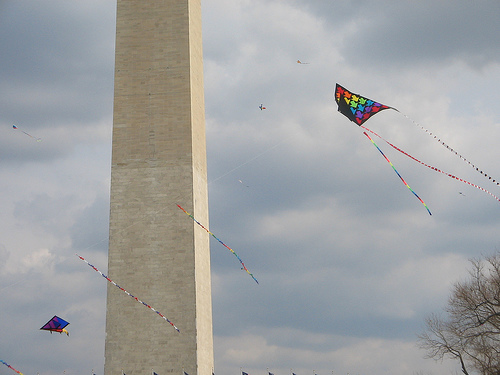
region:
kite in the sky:
[323, 84, 424, 161]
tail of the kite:
[158, 201, 260, 308]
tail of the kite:
[78, 255, 178, 328]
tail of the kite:
[353, 149, 424, 228]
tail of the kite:
[403, 160, 480, 202]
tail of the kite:
[421, 125, 491, 180]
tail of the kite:
[21, 130, 58, 144]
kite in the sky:
[33, 305, 83, 339]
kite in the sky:
[3, 118, 21, 141]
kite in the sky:
[307, 78, 389, 133]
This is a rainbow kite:
[317, 60, 497, 222]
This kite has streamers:
[353, 100, 494, 221]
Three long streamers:
[350, 87, 497, 229]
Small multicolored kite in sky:
[30, 309, 77, 342]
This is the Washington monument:
[102, 0, 229, 374]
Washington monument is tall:
[107, 0, 234, 374]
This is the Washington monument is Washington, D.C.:
[95, 2, 232, 373]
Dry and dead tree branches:
[408, 252, 494, 372]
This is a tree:
[418, 250, 495, 372]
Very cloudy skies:
[2, 3, 497, 373]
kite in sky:
[318, 73, 403, 130]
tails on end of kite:
[360, 107, 497, 222]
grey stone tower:
[85, 1, 222, 372]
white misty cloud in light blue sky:
[246, 186, 386, 268]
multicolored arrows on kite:
[344, 95, 369, 114]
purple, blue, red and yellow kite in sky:
[28, 304, 79, 341]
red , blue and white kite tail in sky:
[75, 236, 196, 343]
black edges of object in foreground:
[146, 364, 309, 374]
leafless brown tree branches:
[406, 253, 498, 373]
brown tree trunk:
[454, 352, 469, 374]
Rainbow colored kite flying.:
[331, 77, 497, 237]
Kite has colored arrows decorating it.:
[325, 76, 427, 170]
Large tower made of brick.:
[100, 0, 241, 372]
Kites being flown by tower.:
[79, 14, 474, 259]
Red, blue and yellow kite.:
[30, 293, 97, 364]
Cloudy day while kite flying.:
[5, 16, 437, 269]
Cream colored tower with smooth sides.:
[89, 2, 250, 367]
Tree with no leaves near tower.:
[390, 236, 498, 373]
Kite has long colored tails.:
[312, 66, 497, 254]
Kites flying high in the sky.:
[0, 15, 327, 180]